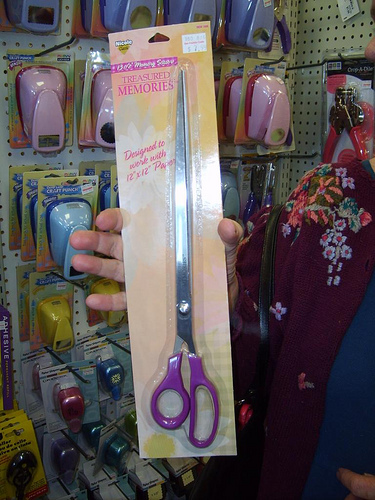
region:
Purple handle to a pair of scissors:
[143, 352, 234, 455]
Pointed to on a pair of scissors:
[174, 64, 190, 89]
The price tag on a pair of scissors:
[178, 28, 213, 57]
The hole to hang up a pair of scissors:
[143, 27, 175, 48]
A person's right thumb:
[217, 210, 247, 248]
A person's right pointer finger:
[93, 205, 134, 232]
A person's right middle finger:
[68, 229, 128, 256]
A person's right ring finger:
[72, 252, 128, 284]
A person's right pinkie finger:
[85, 288, 131, 315]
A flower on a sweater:
[271, 300, 290, 327]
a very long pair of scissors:
[113, 38, 253, 444]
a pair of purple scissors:
[142, 55, 238, 445]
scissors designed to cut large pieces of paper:
[129, 102, 223, 457]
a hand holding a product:
[67, 200, 256, 326]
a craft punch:
[27, 177, 119, 289]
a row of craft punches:
[7, 165, 115, 289]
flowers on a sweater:
[252, 151, 374, 283]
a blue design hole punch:
[78, 335, 140, 421]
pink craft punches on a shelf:
[21, 354, 106, 450]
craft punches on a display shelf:
[5, 157, 151, 487]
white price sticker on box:
[180, 30, 203, 50]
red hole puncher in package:
[36, 360, 98, 426]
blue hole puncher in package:
[82, 333, 133, 400]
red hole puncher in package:
[19, 348, 52, 416]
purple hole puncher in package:
[40, 426, 76, 479]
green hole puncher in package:
[91, 412, 129, 475]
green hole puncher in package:
[115, 397, 135, 438]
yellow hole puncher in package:
[25, 270, 73, 348]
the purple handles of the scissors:
[149, 351, 220, 449]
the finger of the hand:
[335, 464, 373, 496]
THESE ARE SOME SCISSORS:
[146, 67, 222, 448]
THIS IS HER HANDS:
[65, 205, 242, 313]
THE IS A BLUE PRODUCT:
[30, 175, 99, 280]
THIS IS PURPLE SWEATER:
[235, 157, 373, 496]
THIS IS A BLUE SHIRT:
[304, 278, 372, 499]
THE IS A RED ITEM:
[321, 54, 372, 173]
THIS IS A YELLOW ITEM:
[28, 272, 75, 353]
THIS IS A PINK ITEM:
[6, 51, 74, 155]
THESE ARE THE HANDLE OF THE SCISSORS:
[148, 355, 220, 449]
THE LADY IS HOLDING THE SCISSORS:
[64, 20, 244, 458]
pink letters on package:
[116, 72, 179, 95]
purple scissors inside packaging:
[104, 22, 241, 458]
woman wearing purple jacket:
[225, 147, 371, 496]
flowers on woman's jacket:
[267, 163, 373, 325]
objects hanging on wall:
[0, 1, 303, 498]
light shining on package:
[153, 54, 230, 270]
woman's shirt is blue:
[308, 277, 373, 496]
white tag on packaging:
[181, 32, 206, 59]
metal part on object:
[329, 85, 364, 131]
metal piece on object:
[174, 301, 192, 316]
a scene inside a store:
[11, 11, 358, 484]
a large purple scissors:
[98, 18, 258, 471]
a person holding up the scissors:
[61, 13, 373, 498]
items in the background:
[5, 3, 295, 496]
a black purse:
[193, 201, 289, 497]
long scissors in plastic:
[105, 17, 240, 458]